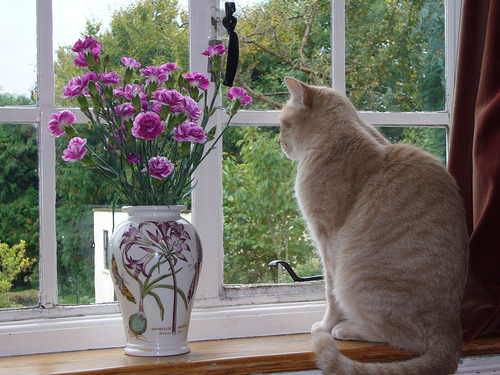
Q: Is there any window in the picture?
A: Yes, there is a window.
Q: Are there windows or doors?
A: Yes, there is a window.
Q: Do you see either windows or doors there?
A: Yes, there is a window.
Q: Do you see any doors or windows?
A: Yes, there is a window.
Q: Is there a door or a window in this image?
A: Yes, there is a window.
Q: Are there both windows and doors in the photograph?
A: No, there is a window but no doors.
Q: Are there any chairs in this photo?
A: No, there are no chairs.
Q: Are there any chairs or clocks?
A: No, there are no chairs or clocks.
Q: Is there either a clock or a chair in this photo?
A: No, there are no chairs or clocks.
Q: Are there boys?
A: No, there are no boys.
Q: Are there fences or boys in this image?
A: No, there are no boys or fences.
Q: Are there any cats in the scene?
A: Yes, there is a cat.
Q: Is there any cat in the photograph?
A: Yes, there is a cat.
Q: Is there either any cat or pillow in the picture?
A: Yes, there is a cat.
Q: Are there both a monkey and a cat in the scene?
A: No, there is a cat but no monkeys.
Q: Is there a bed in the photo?
A: No, there are no beds.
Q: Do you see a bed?
A: No, there are no beds.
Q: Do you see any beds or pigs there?
A: No, there are no beds or pigs.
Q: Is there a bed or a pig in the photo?
A: No, there are no beds or pigs.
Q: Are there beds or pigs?
A: No, there are no beds or pigs.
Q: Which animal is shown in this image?
A: The animal is a cat.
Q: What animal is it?
A: The animal is a cat.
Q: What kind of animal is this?
A: That is a cat.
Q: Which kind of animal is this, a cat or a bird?
A: That is a cat.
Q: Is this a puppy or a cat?
A: This is a cat.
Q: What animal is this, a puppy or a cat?
A: This is a cat.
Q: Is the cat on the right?
A: Yes, the cat is on the right of the image.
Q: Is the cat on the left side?
A: No, the cat is on the right of the image.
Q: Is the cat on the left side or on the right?
A: The cat is on the right of the image.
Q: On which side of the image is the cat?
A: The cat is on the right of the image.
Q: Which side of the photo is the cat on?
A: The cat is on the right of the image.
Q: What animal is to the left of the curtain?
A: The animal is a cat.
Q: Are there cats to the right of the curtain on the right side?
A: No, the cat is to the left of the curtain.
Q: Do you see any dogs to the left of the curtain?
A: No, there is a cat to the left of the curtain.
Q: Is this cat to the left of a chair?
A: No, the cat is to the left of the curtain.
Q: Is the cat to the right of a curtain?
A: No, the cat is to the left of a curtain.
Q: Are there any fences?
A: No, there are no fences.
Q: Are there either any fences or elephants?
A: No, there are no fences or elephants.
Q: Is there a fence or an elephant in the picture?
A: No, there are no fences or elephants.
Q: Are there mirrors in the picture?
A: No, there are no mirrors.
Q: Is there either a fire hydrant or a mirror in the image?
A: No, there are no mirrors or fire hydrants.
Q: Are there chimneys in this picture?
A: No, there are no chimneys.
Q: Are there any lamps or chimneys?
A: No, there are no chimneys or lamps.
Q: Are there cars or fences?
A: No, there are no fences or cars.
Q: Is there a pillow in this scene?
A: No, there are no pillows.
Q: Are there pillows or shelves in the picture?
A: No, there are no pillows or shelves.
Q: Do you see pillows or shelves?
A: No, there are no pillows or shelves.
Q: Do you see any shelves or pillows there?
A: No, there are no pillows or shelves.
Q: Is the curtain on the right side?
A: Yes, the curtain is on the right of the image.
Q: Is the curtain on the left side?
A: No, the curtain is on the right of the image.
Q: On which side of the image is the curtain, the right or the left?
A: The curtain is on the right of the image.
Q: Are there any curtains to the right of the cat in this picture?
A: Yes, there is a curtain to the right of the cat.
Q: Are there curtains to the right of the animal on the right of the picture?
A: Yes, there is a curtain to the right of the cat.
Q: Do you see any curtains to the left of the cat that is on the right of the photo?
A: No, the curtain is to the right of the cat.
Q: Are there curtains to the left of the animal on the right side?
A: No, the curtain is to the right of the cat.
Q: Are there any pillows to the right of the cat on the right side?
A: No, there is a curtain to the right of the cat.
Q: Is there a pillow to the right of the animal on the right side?
A: No, there is a curtain to the right of the cat.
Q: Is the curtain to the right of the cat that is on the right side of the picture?
A: Yes, the curtain is to the right of the cat.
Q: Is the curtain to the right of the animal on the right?
A: Yes, the curtain is to the right of the cat.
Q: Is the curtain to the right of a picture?
A: No, the curtain is to the right of the cat.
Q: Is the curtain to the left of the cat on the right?
A: No, the curtain is to the right of the cat.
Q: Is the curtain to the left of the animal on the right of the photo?
A: No, the curtain is to the right of the cat.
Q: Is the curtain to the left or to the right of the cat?
A: The curtain is to the right of the cat.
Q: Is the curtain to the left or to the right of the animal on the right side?
A: The curtain is to the right of the cat.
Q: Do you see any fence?
A: No, there are no fences.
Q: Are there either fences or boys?
A: No, there are no fences or boys.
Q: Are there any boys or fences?
A: No, there are no fences or boys.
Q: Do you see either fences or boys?
A: No, there are no fences or boys.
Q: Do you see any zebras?
A: No, there are no zebras.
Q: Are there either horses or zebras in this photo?
A: No, there are no zebras or horses.